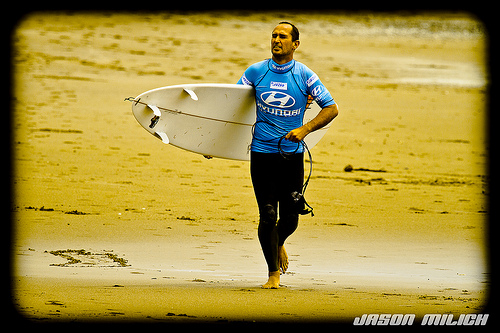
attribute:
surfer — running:
[237, 15, 328, 296]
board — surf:
[126, 47, 356, 173]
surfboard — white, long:
[131, 78, 253, 168]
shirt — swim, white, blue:
[254, 63, 326, 156]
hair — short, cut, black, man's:
[295, 30, 309, 40]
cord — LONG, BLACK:
[274, 133, 315, 190]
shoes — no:
[259, 250, 290, 290]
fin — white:
[164, 84, 208, 113]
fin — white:
[141, 91, 175, 127]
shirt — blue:
[243, 57, 322, 160]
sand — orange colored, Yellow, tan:
[14, 11, 483, 316]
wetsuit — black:
[218, 68, 310, 256]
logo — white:
[259, 88, 297, 109]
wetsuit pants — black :
[250, 149, 305, 276]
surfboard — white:
[127, 83, 333, 163]